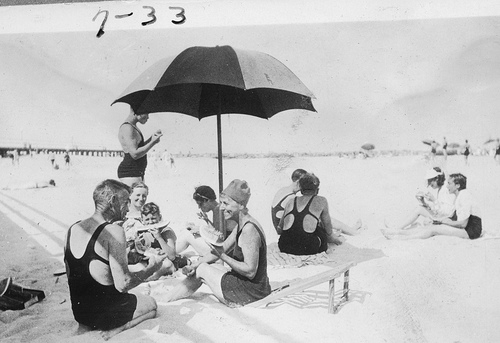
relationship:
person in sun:
[106, 104, 164, 199] [4, 30, 500, 142]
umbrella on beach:
[108, 37, 336, 132] [6, 153, 498, 342]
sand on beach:
[8, 154, 491, 339] [6, 153, 498, 342]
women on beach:
[277, 171, 347, 254] [6, 153, 498, 342]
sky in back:
[3, 35, 499, 148] [4, 37, 498, 131]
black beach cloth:
[4, 277, 49, 314] [0, 272, 53, 303]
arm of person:
[121, 129, 162, 155] [116, 104, 164, 187]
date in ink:
[88, 6, 194, 34] [91, 7, 198, 50]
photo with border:
[2, 8, 499, 341] [0, 5, 499, 36]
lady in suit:
[164, 179, 270, 309] [205, 223, 273, 306]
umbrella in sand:
[108, 37, 336, 132] [8, 154, 491, 339]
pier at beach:
[3, 143, 129, 163] [6, 153, 498, 342]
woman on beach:
[121, 180, 149, 266] [6, 153, 498, 342]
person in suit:
[116, 104, 164, 187] [205, 223, 273, 306]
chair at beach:
[257, 250, 356, 307] [6, 153, 498, 342]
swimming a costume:
[159, 152, 497, 164] [113, 119, 150, 182]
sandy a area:
[0, 154, 491, 319] [1, 154, 499, 340]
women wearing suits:
[277, 171, 347, 254] [63, 123, 155, 331]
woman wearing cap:
[127, 180, 149, 226] [224, 179, 263, 207]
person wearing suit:
[116, 104, 164, 187] [205, 223, 273, 306]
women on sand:
[260, 162, 365, 254] [8, 154, 491, 339]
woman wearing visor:
[127, 180, 149, 226] [422, 165, 443, 180]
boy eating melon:
[132, 199, 186, 260] [129, 220, 173, 233]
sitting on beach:
[393, 179, 493, 252] [6, 153, 498, 342]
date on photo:
[88, 6, 194, 34] [2, 8, 499, 341]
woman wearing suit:
[127, 180, 149, 226] [205, 223, 273, 306]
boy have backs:
[133, 201, 178, 262] [66, 123, 105, 280]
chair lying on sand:
[243, 262, 356, 314] [0, 154, 499, 342]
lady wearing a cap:
[185, 179, 269, 302] [224, 179, 263, 207]